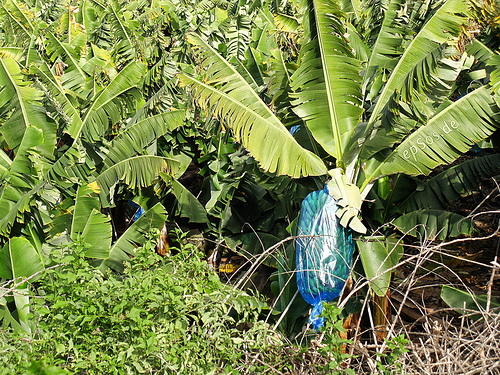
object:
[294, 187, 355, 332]
object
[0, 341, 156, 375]
grass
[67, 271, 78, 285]
leaves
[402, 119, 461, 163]
writing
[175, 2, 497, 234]
tree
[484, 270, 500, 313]
branches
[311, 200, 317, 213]
bananas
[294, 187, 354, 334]
bag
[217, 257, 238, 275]
spot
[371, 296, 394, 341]
trunk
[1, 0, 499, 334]
vegetation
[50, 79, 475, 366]
field